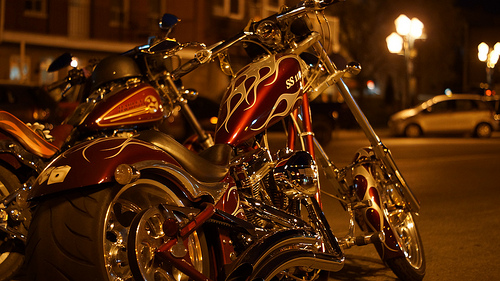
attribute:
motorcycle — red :
[2, 12, 213, 279]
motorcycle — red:
[37, 6, 444, 266]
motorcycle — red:
[6, 26, 239, 271]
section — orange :
[2, 107, 59, 159]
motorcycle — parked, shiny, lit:
[30, 0, 427, 278]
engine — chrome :
[223, 139, 324, 231]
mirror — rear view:
[44, 51, 79, 73]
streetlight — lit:
[386, 13, 422, 107]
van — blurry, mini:
[387, 87, 494, 144]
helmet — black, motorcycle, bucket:
[84, 46, 147, 94]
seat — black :
[145, 129, 239, 181]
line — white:
[378, 147, 498, 167]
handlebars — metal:
[172, 1, 361, 107]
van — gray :
[385, 86, 494, 138]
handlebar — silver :
[171, 1, 326, 80]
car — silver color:
[390, 90, 499, 141]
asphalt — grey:
[263, 129, 494, 276]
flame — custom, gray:
[220, 48, 307, 144]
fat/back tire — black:
[32, 172, 210, 279]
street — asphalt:
[319, 124, 499, 275]